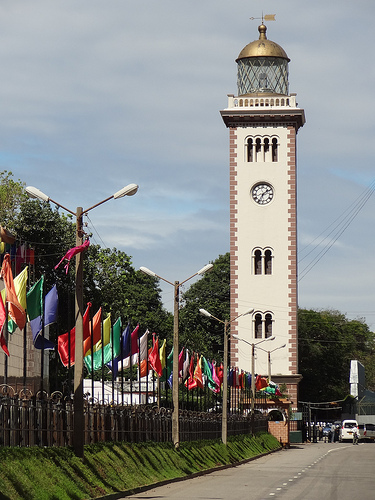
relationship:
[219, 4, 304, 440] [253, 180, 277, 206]
building with clock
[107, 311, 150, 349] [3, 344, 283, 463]
flag on fence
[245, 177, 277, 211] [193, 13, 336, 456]
clock on building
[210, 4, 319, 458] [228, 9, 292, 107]
building has top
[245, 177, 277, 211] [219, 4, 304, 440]
clock on building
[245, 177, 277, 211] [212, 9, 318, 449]
clock on building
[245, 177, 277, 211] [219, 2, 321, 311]
clock on building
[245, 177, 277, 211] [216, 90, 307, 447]
clock on building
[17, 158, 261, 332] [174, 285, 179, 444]
lights are on pole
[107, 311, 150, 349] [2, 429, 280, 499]
flag have shadows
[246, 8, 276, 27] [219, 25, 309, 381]
weather vane standing on top of building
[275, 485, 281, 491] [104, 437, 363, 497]
line dividing road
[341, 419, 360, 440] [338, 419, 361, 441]
back end belonging to van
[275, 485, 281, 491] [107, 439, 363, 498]
line painted on street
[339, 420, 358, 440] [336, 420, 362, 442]
back belonging to van